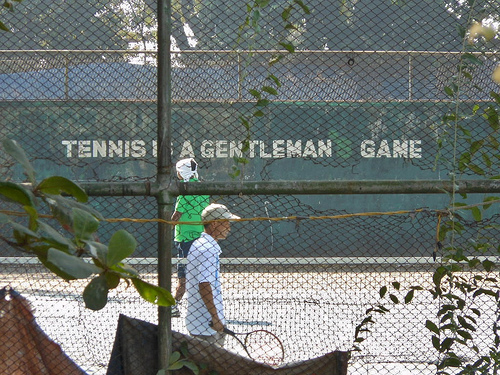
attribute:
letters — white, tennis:
[58, 137, 146, 161]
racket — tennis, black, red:
[201, 318, 289, 367]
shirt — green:
[173, 183, 208, 237]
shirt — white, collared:
[183, 232, 241, 340]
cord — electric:
[5, 205, 497, 233]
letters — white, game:
[357, 136, 446, 163]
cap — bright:
[198, 200, 242, 224]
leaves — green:
[0, 136, 177, 306]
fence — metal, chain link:
[3, 3, 499, 374]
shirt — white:
[182, 231, 230, 335]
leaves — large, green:
[2, 163, 179, 314]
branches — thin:
[343, 239, 499, 374]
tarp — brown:
[104, 312, 349, 374]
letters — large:
[61, 136, 424, 165]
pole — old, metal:
[153, 0, 174, 371]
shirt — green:
[172, 176, 211, 242]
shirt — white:
[186, 232, 226, 335]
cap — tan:
[203, 194, 243, 234]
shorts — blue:
[166, 231, 213, 280]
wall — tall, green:
[39, 82, 497, 265]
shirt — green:
[152, 176, 233, 239]